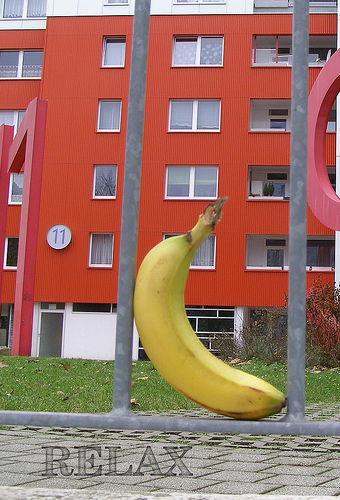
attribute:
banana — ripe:
[133, 194, 288, 419]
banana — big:
[123, 184, 310, 484]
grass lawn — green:
[2, 349, 339, 424]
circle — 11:
[45, 223, 71, 251]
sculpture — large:
[0, 94, 51, 355]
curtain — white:
[173, 41, 195, 62]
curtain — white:
[200, 41, 221, 63]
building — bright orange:
[95, 6, 240, 216]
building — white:
[31, 301, 286, 358]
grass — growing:
[39, 422, 339, 447]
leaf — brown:
[128, 390, 144, 409]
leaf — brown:
[227, 353, 242, 363]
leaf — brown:
[52, 385, 66, 398]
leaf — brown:
[130, 372, 152, 382]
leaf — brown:
[11, 361, 27, 373]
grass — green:
[2, 353, 200, 414]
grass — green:
[234, 357, 337, 403]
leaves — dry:
[0, 351, 339, 419]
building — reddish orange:
[46, 22, 92, 160]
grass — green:
[1, 353, 339, 413]